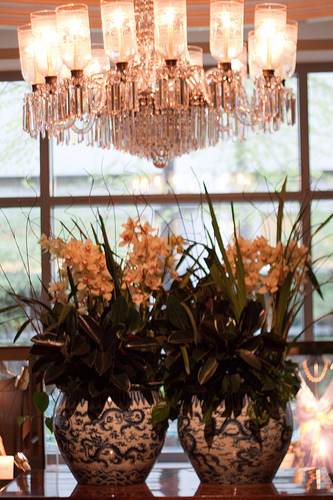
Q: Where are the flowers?
A: In the vases.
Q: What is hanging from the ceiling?
A: The chandelier.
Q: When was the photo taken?
A: In the morning.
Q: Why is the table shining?
A: From the light reflecting from the chandelier.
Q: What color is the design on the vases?
A: Blue.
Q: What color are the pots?
A: Blue and white.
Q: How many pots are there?
A: 2.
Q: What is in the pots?
A: Plants.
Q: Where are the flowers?
A: In pots.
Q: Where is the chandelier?
A: Above the plants.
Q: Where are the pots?
A: On a table.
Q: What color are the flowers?
A: White.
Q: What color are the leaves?
A: Green.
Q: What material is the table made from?
A: Wood.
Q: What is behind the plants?
A: Window.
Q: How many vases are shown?
A: 2.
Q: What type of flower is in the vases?
A: Orchid.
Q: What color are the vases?
A: Blue and white.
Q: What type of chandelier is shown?
A: Glass.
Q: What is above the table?
A: Chandelier.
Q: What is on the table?
A: Plants.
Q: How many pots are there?
A: Two.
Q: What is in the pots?
A: Flowers.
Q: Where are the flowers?
A: On table.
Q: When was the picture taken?
A: Daytime.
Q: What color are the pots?
A: Blue and white.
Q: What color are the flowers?
A: White.